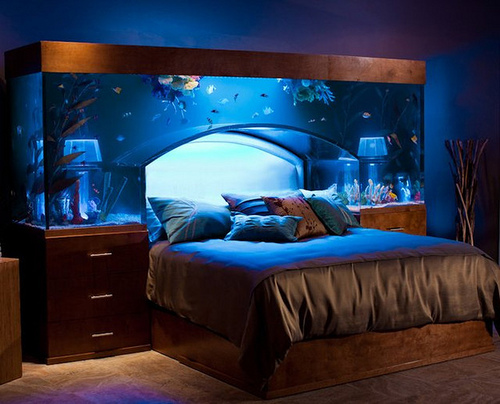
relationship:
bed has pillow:
[141, 238, 494, 388] [145, 195, 234, 247]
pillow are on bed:
[145, 195, 234, 247] [141, 238, 494, 388]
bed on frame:
[141, 238, 494, 388] [153, 320, 488, 394]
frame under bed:
[153, 320, 488, 394] [141, 238, 494, 388]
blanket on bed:
[151, 256, 431, 304] [141, 238, 494, 388]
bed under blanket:
[141, 238, 494, 388] [151, 256, 431, 304]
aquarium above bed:
[25, 35, 433, 221] [141, 238, 494, 388]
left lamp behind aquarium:
[55, 139, 105, 225] [25, 35, 433, 221]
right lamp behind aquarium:
[344, 124, 407, 197] [25, 35, 433, 221]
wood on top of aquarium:
[15, 29, 437, 104] [25, 35, 433, 221]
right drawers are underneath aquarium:
[357, 214, 434, 242] [25, 35, 433, 221]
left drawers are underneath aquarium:
[26, 237, 168, 353] [25, 35, 433, 221]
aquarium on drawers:
[25, 35, 433, 221] [31, 234, 462, 313]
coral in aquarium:
[359, 180, 398, 203] [25, 35, 433, 221]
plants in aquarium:
[12, 87, 95, 219] [25, 35, 433, 221]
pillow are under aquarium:
[145, 195, 234, 247] [25, 35, 433, 221]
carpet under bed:
[286, 389, 480, 402] [141, 238, 494, 388]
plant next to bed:
[422, 140, 498, 273] [141, 238, 494, 388]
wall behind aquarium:
[13, 11, 425, 67] [25, 35, 433, 221]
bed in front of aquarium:
[141, 238, 494, 388] [25, 35, 433, 221]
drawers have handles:
[31, 234, 462, 313] [73, 249, 126, 267]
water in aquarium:
[50, 86, 131, 145] [25, 35, 433, 221]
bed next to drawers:
[141, 238, 494, 388] [31, 234, 462, 313]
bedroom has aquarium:
[11, 11, 485, 390] [25, 35, 433, 221]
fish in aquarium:
[382, 184, 405, 199] [25, 35, 433, 221]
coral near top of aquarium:
[272, 81, 344, 110] [25, 35, 433, 221]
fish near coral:
[361, 108, 377, 126] [272, 81, 344, 110]